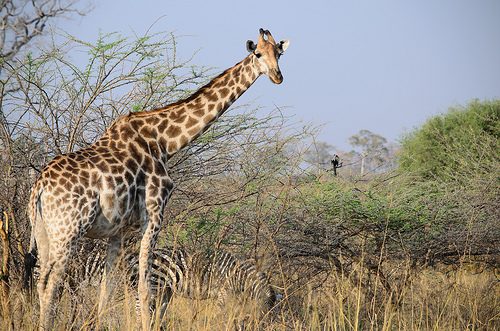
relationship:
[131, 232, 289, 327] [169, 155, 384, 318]
zebra behind bush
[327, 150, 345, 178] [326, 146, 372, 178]
bird on limb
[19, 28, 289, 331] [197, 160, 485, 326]
animals by brush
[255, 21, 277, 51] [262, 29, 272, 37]
horns have black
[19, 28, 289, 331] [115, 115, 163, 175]
animals has shoulders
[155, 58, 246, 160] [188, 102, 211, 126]
neck has spots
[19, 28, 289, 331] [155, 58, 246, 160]
animals has neck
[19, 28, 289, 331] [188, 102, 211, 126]
animals has spots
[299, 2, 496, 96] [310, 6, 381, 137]
sky has haze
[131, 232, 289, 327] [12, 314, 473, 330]
zebra eating grass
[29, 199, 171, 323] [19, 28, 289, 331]
legs of animals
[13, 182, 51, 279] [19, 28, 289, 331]
tail of animals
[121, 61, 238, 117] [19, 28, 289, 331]
mane of animals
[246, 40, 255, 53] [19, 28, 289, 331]
ear of animals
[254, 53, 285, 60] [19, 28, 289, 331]
eyes of animals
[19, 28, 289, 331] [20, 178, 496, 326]
animals in field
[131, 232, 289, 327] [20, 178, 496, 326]
zebra in field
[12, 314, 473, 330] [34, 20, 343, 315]
grass by animals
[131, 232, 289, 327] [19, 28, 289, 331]
zebra behind animals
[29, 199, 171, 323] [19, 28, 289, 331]
legs on animals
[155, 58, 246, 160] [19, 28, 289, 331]
neck of animals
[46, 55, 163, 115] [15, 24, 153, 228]
branches on tree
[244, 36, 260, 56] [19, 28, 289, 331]
ear of animals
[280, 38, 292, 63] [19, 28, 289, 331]
ear of animals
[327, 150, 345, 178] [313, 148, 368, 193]
bird on branch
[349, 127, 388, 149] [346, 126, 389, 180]
branches on tree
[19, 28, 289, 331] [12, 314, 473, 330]
animals in grass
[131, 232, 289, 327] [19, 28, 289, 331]
zebra by animals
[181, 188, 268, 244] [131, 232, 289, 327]
bush behind zebra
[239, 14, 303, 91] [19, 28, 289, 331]
head of animals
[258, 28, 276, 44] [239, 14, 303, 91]
horns on head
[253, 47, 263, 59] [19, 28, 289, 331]
eye of animals